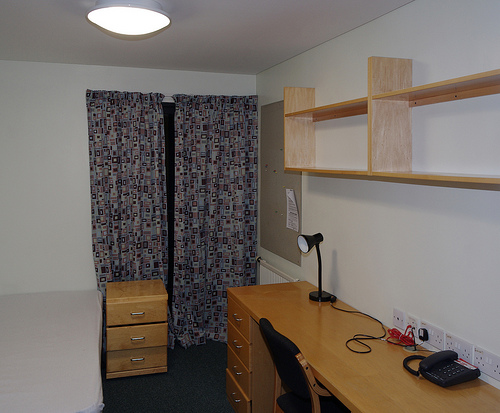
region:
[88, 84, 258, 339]
black and white curtains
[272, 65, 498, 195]
empty shelves on wall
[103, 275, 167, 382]
three drawer dresser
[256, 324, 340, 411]
black chair pushed under desk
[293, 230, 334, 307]
black lamp on desk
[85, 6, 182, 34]
light on white ceiling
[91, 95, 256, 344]
long curtains covering window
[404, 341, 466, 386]
black telephone on desk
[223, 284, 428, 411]
desk with four drawers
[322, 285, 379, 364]
black cord of lamp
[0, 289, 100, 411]
A twin bed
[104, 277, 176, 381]
A brown nightstand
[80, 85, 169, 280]
A curtain panel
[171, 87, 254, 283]
A curtain panel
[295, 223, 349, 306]
A black desk lamp on the desk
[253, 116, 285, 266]
A bulletin board on the wall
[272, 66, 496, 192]
A set of shelves on the wall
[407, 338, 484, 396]
A black telephone on the desk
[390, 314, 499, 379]
A row of electrical outlets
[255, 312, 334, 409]
A black desk chair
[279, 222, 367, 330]
A Black Desk Lamp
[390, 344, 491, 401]
A Corded Black Telephone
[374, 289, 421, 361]
A Neatly tied Bundle of red cords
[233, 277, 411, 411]
A Rather empty Desktop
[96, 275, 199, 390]
A Small Wooden Dresser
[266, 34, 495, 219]
Empty Shelves attached to the Wall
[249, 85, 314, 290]
Bulletin Board with only one thing posted on it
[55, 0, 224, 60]
A White Ceiling Light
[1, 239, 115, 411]
An Unmade up Bed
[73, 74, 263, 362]
Blue Curtains with a repeating squares motif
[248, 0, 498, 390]
The shelf is hanging on the wall.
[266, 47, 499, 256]
The shelf is made from wood.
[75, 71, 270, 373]
The curtains are long.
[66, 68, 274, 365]
The curtains are closed.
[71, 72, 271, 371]
The window has curtains.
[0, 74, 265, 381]
The nightstand is in front of the curtains.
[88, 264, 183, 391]
The nightstand is made from wood.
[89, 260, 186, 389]
The nightstand has three drawers.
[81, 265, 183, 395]
The nightstand drawers have drawer pulls.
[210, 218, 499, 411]
The lamp in on the desk.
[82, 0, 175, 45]
white light on the ceiling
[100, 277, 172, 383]
brown nightstand with silver handles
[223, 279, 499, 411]
brown desk with silver handles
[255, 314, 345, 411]
black and brown desk chair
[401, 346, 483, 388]
black telephone on the desk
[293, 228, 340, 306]
black and white lamp on the desk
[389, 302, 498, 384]
white outlets by the desk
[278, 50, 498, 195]
brown wooden shelf on the wall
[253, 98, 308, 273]
cork board with a white frame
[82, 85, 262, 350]
curtains with a pattern